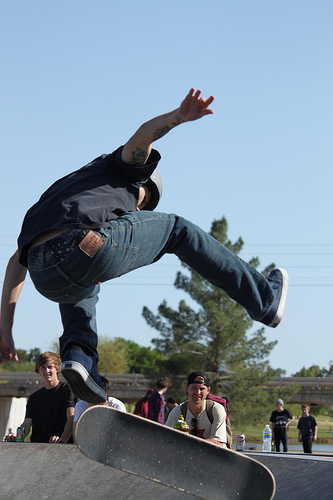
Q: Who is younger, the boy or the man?
A: The boy is younger than the man.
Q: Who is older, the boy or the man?
A: The man is older than the boy.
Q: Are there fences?
A: No, there are no fences.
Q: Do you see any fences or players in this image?
A: No, there are no fences or players.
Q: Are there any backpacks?
A: Yes, there is a backpack.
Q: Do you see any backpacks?
A: Yes, there is a backpack.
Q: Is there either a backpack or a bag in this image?
A: Yes, there is a backpack.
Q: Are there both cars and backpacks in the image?
A: No, there is a backpack but no cars.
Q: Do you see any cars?
A: No, there are no cars.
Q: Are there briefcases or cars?
A: No, there are no cars or briefcases.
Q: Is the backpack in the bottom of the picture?
A: Yes, the backpack is in the bottom of the image.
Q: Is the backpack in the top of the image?
A: No, the backpack is in the bottom of the image.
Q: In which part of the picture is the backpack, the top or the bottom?
A: The backpack is in the bottom of the image.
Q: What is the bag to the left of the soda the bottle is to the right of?
A: The bag is a backpack.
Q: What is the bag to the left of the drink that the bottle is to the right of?
A: The bag is a backpack.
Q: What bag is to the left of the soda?
A: The bag is a backpack.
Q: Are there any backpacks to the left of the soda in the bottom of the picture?
A: Yes, there is a backpack to the left of the soda.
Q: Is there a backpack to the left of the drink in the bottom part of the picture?
A: Yes, there is a backpack to the left of the soda.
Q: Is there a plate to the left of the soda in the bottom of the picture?
A: No, there is a backpack to the left of the soda.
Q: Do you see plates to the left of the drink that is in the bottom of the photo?
A: No, there is a backpack to the left of the soda.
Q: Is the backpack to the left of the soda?
A: Yes, the backpack is to the left of the soda.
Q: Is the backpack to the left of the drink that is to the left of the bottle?
A: Yes, the backpack is to the left of the soda.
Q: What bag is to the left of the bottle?
A: The bag is a backpack.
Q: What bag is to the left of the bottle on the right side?
A: The bag is a backpack.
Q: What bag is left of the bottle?
A: The bag is a backpack.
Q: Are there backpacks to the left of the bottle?
A: Yes, there is a backpack to the left of the bottle.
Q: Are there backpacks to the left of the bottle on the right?
A: Yes, there is a backpack to the left of the bottle.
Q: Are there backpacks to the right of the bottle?
A: No, the backpack is to the left of the bottle.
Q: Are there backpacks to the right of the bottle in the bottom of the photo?
A: No, the backpack is to the left of the bottle.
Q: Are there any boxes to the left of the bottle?
A: No, there is a backpack to the left of the bottle.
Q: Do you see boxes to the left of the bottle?
A: No, there is a backpack to the left of the bottle.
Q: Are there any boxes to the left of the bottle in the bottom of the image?
A: No, there is a backpack to the left of the bottle.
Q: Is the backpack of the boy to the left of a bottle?
A: Yes, the backpack is to the left of a bottle.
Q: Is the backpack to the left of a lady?
A: No, the backpack is to the left of a bottle.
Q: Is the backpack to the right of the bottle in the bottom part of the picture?
A: No, the backpack is to the left of the bottle.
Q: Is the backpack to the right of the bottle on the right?
A: No, the backpack is to the left of the bottle.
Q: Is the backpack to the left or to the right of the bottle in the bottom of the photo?
A: The backpack is to the left of the bottle.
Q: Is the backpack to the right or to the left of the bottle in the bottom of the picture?
A: The backpack is to the left of the bottle.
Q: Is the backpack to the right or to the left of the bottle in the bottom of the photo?
A: The backpack is to the left of the bottle.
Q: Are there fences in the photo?
A: No, there are no fences.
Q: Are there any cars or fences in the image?
A: No, there are no fences or cars.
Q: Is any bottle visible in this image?
A: Yes, there is a bottle.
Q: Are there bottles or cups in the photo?
A: Yes, there is a bottle.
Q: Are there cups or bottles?
A: Yes, there is a bottle.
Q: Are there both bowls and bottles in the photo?
A: No, there is a bottle but no bowls.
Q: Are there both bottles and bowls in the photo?
A: No, there is a bottle but no bowls.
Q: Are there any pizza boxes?
A: No, there are no pizza boxes.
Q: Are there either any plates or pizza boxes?
A: No, there are no pizza boxes or plates.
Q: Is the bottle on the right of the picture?
A: Yes, the bottle is on the right of the image.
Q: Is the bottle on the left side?
A: No, the bottle is on the right of the image.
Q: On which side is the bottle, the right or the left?
A: The bottle is on the right of the image.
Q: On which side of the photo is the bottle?
A: The bottle is on the right of the image.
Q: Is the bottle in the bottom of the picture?
A: Yes, the bottle is in the bottom of the image.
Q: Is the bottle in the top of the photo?
A: No, the bottle is in the bottom of the image.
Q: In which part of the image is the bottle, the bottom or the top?
A: The bottle is in the bottom of the image.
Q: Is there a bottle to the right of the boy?
A: Yes, there is a bottle to the right of the boy.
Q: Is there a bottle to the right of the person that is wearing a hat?
A: Yes, there is a bottle to the right of the boy.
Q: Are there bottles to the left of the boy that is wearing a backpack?
A: No, the bottle is to the right of the boy.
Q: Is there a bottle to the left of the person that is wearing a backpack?
A: No, the bottle is to the right of the boy.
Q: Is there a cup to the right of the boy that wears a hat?
A: No, there is a bottle to the right of the boy.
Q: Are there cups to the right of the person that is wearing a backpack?
A: No, there is a bottle to the right of the boy.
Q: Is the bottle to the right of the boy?
A: Yes, the bottle is to the right of the boy.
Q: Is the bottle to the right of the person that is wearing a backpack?
A: Yes, the bottle is to the right of the boy.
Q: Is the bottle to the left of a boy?
A: No, the bottle is to the right of a boy.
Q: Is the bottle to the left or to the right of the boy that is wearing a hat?
A: The bottle is to the right of the boy.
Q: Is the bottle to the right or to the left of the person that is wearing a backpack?
A: The bottle is to the right of the boy.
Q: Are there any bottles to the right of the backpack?
A: Yes, there is a bottle to the right of the backpack.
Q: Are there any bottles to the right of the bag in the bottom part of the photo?
A: Yes, there is a bottle to the right of the backpack.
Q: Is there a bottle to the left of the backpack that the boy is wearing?
A: No, the bottle is to the right of the backpack.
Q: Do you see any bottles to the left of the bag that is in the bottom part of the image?
A: No, the bottle is to the right of the backpack.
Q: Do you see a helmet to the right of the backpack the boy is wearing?
A: No, there is a bottle to the right of the backpack.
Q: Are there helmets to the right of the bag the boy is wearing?
A: No, there is a bottle to the right of the backpack.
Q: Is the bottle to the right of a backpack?
A: Yes, the bottle is to the right of a backpack.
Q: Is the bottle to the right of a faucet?
A: No, the bottle is to the right of a backpack.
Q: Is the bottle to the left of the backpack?
A: No, the bottle is to the right of the backpack.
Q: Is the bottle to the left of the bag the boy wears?
A: No, the bottle is to the right of the backpack.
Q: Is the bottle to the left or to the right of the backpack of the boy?
A: The bottle is to the right of the backpack.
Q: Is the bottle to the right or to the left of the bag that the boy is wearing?
A: The bottle is to the right of the backpack.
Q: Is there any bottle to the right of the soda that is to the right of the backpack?
A: Yes, there is a bottle to the right of the soda.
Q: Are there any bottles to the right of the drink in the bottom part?
A: Yes, there is a bottle to the right of the soda.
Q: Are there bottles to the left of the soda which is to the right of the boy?
A: No, the bottle is to the right of the soda.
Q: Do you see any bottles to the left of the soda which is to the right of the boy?
A: No, the bottle is to the right of the soda.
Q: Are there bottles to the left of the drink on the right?
A: No, the bottle is to the right of the soda.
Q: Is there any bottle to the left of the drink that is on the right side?
A: No, the bottle is to the right of the soda.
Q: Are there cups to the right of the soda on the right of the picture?
A: No, there is a bottle to the right of the soda.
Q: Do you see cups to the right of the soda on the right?
A: No, there is a bottle to the right of the soda.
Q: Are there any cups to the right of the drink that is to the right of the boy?
A: No, there is a bottle to the right of the soda.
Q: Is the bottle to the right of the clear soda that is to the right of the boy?
A: Yes, the bottle is to the right of the soda.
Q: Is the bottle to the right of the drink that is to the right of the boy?
A: Yes, the bottle is to the right of the soda.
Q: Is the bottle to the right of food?
A: No, the bottle is to the right of the soda.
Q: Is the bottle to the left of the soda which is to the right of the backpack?
A: No, the bottle is to the right of the soda.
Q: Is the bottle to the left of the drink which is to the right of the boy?
A: No, the bottle is to the right of the soda.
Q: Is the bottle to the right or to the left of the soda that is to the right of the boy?
A: The bottle is to the right of the soda.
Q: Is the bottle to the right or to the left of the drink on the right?
A: The bottle is to the right of the soda.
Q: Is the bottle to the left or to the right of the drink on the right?
A: The bottle is to the right of the soda.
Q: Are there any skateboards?
A: Yes, there is a skateboard.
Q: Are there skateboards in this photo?
A: Yes, there is a skateboard.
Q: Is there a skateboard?
A: Yes, there is a skateboard.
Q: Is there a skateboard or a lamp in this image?
A: Yes, there is a skateboard.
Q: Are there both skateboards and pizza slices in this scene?
A: No, there is a skateboard but no pizza slices.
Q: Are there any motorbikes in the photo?
A: No, there are no motorbikes.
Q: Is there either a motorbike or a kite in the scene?
A: No, there are no motorcycles or kites.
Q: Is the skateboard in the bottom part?
A: Yes, the skateboard is in the bottom of the image.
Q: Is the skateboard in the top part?
A: No, the skateboard is in the bottom of the image.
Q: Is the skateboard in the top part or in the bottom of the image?
A: The skateboard is in the bottom of the image.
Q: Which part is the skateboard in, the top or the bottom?
A: The skateboard is in the bottom of the image.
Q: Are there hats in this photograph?
A: Yes, there is a hat.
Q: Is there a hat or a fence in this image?
A: Yes, there is a hat.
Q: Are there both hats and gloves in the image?
A: No, there is a hat but no gloves.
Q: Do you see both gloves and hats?
A: No, there is a hat but no gloves.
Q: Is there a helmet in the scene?
A: No, there are no helmets.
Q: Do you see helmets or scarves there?
A: No, there are no helmets or scarves.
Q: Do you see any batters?
A: No, there are no batters.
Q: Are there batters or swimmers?
A: No, there are no batters or swimmers.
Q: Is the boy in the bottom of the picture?
A: Yes, the boy is in the bottom of the image.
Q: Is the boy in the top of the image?
A: No, the boy is in the bottom of the image.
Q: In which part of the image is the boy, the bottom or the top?
A: The boy is in the bottom of the image.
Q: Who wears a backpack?
A: The boy wears a backpack.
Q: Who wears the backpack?
A: The boy wears a backpack.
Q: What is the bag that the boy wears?
A: The bag is a backpack.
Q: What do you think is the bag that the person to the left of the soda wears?
A: The bag is a backpack.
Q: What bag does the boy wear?
A: The boy wears a backpack.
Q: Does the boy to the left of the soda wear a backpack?
A: Yes, the boy wears a backpack.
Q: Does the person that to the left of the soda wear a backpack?
A: Yes, the boy wears a backpack.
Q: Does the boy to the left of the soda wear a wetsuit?
A: No, the boy wears a backpack.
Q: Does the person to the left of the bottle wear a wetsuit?
A: No, the boy wears a backpack.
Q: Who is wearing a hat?
A: The boy is wearing a hat.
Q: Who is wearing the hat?
A: The boy is wearing a hat.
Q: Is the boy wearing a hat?
A: Yes, the boy is wearing a hat.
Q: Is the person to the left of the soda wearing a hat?
A: Yes, the boy is wearing a hat.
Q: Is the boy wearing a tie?
A: No, the boy is wearing a hat.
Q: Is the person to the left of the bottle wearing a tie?
A: No, the boy is wearing a hat.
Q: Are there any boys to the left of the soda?
A: Yes, there is a boy to the left of the soda.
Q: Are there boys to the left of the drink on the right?
A: Yes, there is a boy to the left of the soda.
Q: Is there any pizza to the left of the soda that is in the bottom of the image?
A: No, there is a boy to the left of the soda.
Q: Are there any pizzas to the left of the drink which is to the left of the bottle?
A: No, there is a boy to the left of the soda.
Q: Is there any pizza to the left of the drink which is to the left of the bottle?
A: No, there is a boy to the left of the soda.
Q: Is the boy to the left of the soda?
A: Yes, the boy is to the left of the soda.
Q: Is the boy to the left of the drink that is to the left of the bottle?
A: Yes, the boy is to the left of the soda.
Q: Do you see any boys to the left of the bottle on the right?
A: Yes, there is a boy to the left of the bottle.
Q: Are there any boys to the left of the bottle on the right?
A: Yes, there is a boy to the left of the bottle.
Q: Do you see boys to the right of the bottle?
A: No, the boy is to the left of the bottle.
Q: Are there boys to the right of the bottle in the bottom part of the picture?
A: No, the boy is to the left of the bottle.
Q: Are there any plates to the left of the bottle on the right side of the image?
A: No, there is a boy to the left of the bottle.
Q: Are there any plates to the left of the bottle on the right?
A: No, there is a boy to the left of the bottle.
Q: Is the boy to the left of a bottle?
A: Yes, the boy is to the left of a bottle.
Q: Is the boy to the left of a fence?
A: No, the boy is to the left of a bottle.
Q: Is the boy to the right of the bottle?
A: No, the boy is to the left of the bottle.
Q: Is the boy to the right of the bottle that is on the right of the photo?
A: No, the boy is to the left of the bottle.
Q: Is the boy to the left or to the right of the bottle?
A: The boy is to the left of the bottle.